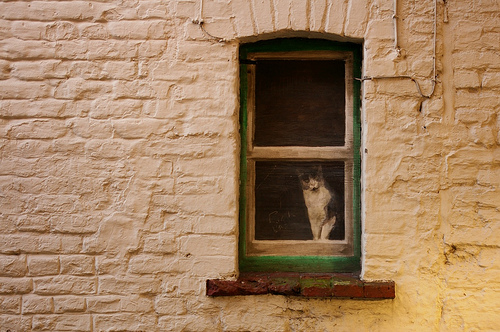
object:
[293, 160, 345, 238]
cat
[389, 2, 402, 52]
conduit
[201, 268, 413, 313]
window ledge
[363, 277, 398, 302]
brick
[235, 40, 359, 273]
window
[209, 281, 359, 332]
framed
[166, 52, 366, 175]
top